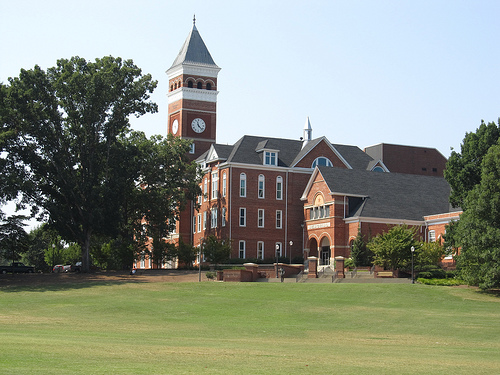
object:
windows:
[255, 239, 266, 260]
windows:
[273, 242, 283, 260]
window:
[259, 152, 278, 165]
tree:
[4, 51, 206, 268]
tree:
[367, 222, 419, 277]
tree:
[440, 115, 498, 296]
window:
[257, 172, 264, 199]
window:
[238, 170, 246, 196]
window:
[274, 208, 283, 229]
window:
[256, 208, 263, 227]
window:
[238, 240, 245, 259]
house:
[316, 165, 451, 218]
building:
[133, 15, 229, 266]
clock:
[188, 117, 211, 135]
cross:
[187, 10, 198, 29]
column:
[334, 256, 345, 276]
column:
[306, 255, 318, 278]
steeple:
[300, 113, 312, 143]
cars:
[0, 261, 84, 275]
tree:
[1, 54, 159, 272]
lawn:
[1, 299, 103, 370]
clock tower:
[161, 7, 233, 163]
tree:
[346, 221, 413, 285]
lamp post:
[409, 244, 415, 284]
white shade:
[410, 245, 415, 251]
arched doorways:
[304, 231, 332, 269]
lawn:
[395, 313, 499, 375]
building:
[228, 131, 476, 276]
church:
[139, 146, 459, 273]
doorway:
[317, 234, 333, 264]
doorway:
[307, 234, 318, 258]